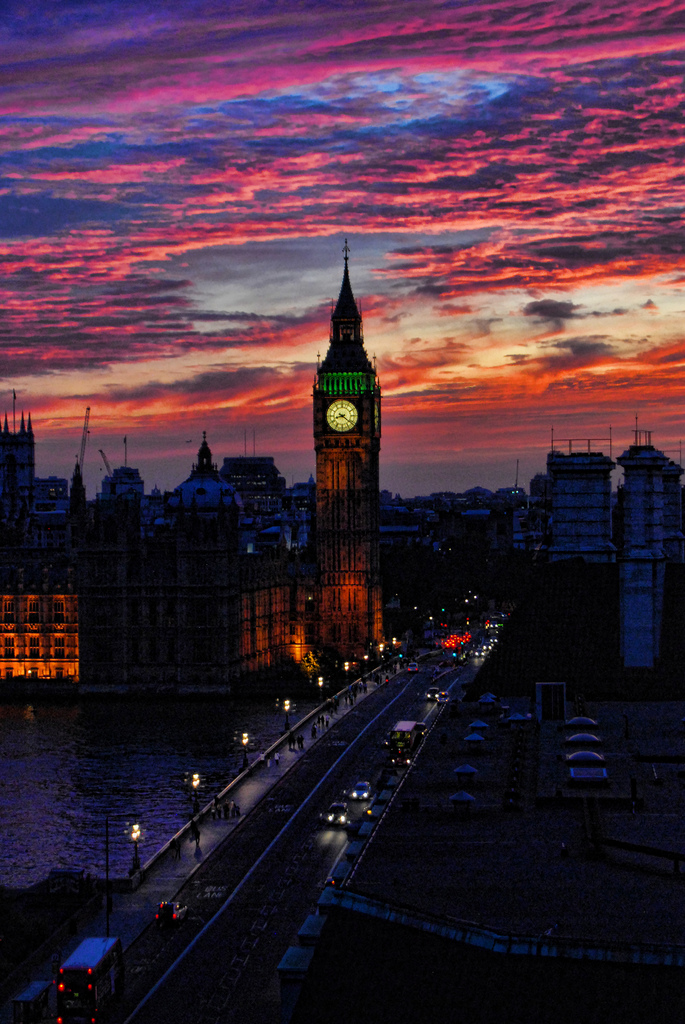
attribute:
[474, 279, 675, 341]
cloud — white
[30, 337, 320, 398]
cloud — white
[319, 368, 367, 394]
lights — green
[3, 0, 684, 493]
sky — sunset, multi colored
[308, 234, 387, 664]
tower — pointed, tall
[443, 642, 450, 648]
tail light — red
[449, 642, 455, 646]
tail light — red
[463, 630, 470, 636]
tail light — red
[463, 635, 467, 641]
tail light — red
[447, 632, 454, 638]
tail light — red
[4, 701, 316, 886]
water — calm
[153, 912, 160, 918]
light — red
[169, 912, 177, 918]
light — red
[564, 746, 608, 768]
car — parked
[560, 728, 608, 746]
car — parked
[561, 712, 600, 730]
car — parked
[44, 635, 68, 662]
window — glassy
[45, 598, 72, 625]
window — glassy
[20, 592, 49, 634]
window — glassy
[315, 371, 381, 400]
lights — green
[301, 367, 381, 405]
lights — green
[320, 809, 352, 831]
headlights — round, illuminated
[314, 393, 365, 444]
clock — round, iluminated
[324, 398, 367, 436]
clock — round, white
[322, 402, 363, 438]
numerals — black, roman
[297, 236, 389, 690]
clock tower — stoned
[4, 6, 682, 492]
clouds — pink, Blue, golden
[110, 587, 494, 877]
lamps — black, metal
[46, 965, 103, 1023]
lights — illuminated, red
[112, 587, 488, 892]
street lamps — illuminated